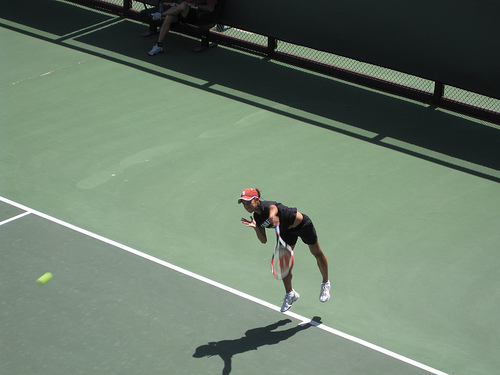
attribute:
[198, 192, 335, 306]
woman — jumping, playing, young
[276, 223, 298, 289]
racket — red, white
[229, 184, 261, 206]
hat — red, white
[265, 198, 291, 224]
shirt — black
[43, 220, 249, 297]
lines — white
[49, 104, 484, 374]
court — green, blue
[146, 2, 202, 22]
person — sitting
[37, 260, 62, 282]
ball — flying, yellow, moving, green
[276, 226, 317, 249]
shorts — black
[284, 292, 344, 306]
tennis shoes — white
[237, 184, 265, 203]
cap — red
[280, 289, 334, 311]
sneakers — white